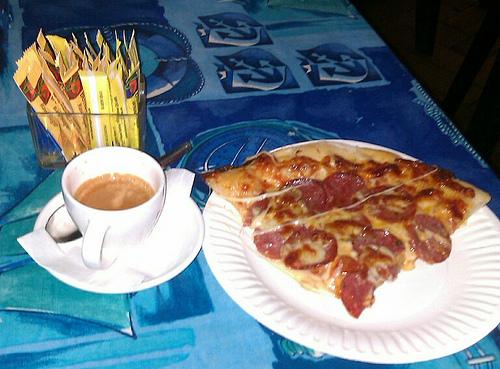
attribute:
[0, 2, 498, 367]
tablecloth — blue, nautical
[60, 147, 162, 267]
cup — white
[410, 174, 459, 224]
cheese — melted 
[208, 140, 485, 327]
pizza — hot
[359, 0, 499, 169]
floor — hardwood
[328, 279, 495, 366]
plate — white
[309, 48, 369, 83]
anchor — blue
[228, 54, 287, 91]
anchor — blue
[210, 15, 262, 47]
anchor — blue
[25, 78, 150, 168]
container — plastic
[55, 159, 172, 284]
napkin — white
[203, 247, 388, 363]
paper plate — white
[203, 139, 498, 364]
plate — white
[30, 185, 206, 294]
saucer — white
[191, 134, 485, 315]
pizza — piece, cool